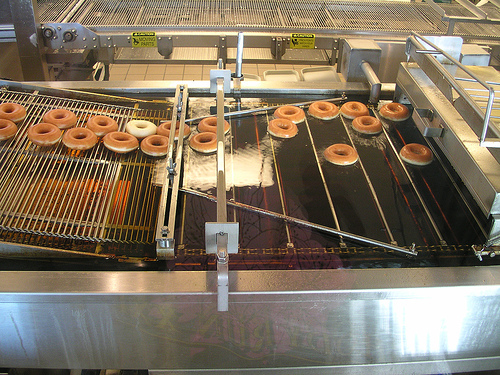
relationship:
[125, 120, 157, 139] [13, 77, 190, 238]
donut on belt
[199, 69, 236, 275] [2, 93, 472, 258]
rod across belt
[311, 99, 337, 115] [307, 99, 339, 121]
top of donut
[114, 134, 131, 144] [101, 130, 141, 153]
center of donut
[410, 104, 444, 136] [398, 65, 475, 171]
handle on machinery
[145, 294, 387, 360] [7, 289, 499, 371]
reflection on surface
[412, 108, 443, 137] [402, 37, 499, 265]
handle on mechanism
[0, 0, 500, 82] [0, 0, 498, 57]
machine of machine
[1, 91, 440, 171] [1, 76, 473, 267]
donuts on conveyor belt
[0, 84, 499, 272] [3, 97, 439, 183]
grease underneath donuts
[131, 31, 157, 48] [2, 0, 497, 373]
warning label on equipment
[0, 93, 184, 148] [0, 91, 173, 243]
donut on conveyor belt.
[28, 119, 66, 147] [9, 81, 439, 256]
donut on conveyor belt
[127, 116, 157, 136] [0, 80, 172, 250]
donut on belt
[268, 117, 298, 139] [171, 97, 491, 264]
donut on belt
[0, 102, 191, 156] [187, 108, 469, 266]
donut going into grease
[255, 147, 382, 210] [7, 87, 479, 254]
grease underneath conveyor belt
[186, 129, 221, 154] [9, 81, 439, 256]
donut on conveyor belt